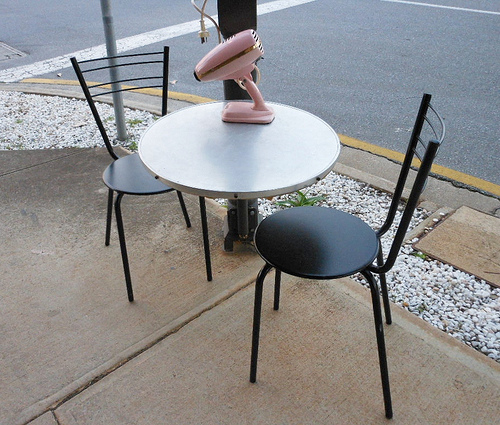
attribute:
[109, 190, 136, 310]
leg — black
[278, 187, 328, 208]
weeds — green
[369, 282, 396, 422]
leg — black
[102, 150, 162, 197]
seat — black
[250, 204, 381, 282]
seat — black, circular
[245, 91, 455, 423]
chair — black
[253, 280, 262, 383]
chair leg — black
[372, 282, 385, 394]
chair leg — black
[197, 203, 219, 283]
chair leg — black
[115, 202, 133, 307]
chair leg — black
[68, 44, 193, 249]
chair — black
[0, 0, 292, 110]
line — thick, white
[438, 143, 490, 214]
line — yellow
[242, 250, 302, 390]
chair leg — black